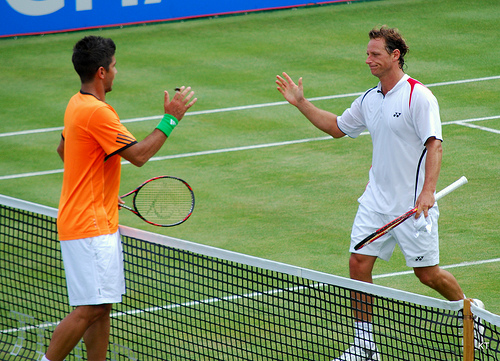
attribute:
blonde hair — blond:
[361, 21, 421, 67]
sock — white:
[347, 315, 377, 343]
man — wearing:
[299, 33, 491, 267]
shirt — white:
[349, 80, 473, 190]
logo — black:
[411, 252, 428, 267]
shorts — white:
[334, 195, 451, 268]